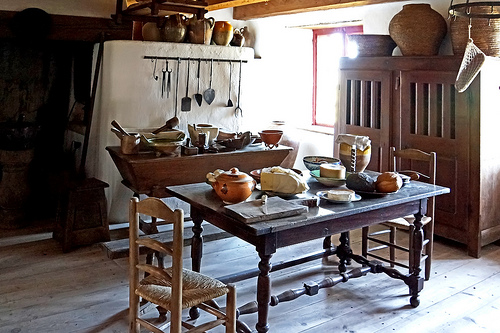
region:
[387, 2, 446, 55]
clay pot on top of cabinet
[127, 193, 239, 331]
wooden chair at table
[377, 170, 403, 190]
round loaf of bread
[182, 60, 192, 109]
spatula hanging on rack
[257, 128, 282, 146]
brown bowl on counter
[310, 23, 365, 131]
red-framed window letting light in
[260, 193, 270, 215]
knife on cutting board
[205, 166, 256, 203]
covered pot on table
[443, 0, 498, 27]
rack hanging from ceiling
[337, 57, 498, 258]
large cabinet in kitchen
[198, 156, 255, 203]
pot with lid on table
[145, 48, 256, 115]
cooking utensils hanging from rack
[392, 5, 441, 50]
woven basket on cabinet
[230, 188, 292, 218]
cutting board with knife on table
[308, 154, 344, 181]
bowl with cheese on the table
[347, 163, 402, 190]
bread on the table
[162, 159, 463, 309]
table full of items in a rustic kitchen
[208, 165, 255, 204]
copper colored tea kettle on the table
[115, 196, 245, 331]
wooden chair with a straw seat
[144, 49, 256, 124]
many cooking implements hanging on the wall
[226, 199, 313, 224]
grey marble cutting board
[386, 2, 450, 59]
large pot on top of a cupboard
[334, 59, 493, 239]
large wooden cupboard with two doors on it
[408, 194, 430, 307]
ornate leg of the big table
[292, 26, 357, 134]
window with bright light shining in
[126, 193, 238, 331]
A wooden dining chair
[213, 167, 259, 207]
A orange piece of pottery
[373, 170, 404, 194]
A piece of brown bread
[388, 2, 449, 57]
A large brown wicker basket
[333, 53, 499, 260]
A large brown wooden pantry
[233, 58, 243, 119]
A large steel fork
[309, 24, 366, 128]
A red framed window in the kitchen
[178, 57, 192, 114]
A large steel spatula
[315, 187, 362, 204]
A medium sized cheese plate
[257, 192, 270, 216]
A large carving knife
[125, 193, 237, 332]
wood chair under table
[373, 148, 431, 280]
wood chair under table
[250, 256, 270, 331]
wood leg of table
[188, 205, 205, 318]
wood leg of table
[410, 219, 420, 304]
wood leg of table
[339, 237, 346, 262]
wood leg of table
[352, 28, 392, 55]
basket on wood cabinet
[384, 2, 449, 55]
basket on wood cabinet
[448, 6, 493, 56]
basket on wood cabinet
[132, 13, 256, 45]
jars on top of wall